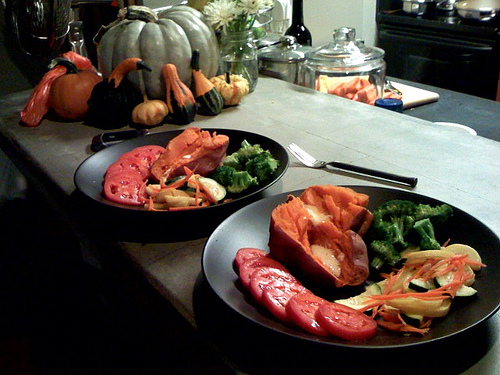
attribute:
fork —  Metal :
[287, 136, 428, 190]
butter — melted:
[308, 244, 340, 277]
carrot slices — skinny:
[367, 252, 482, 325]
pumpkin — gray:
[91, 2, 221, 79]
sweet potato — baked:
[268, 184, 371, 286]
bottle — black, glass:
[288, 3, 312, 43]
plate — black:
[209, 179, 498, 374]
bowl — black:
[205, 188, 499, 353]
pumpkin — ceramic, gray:
[98, 6, 223, 97]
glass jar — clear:
[295, 21, 390, 106]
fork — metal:
[288, 143, 416, 188]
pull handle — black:
[398, 20, 468, 58]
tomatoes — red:
[228, 245, 378, 340]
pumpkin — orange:
[53, 69, 100, 111]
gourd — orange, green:
[185, 43, 226, 118]